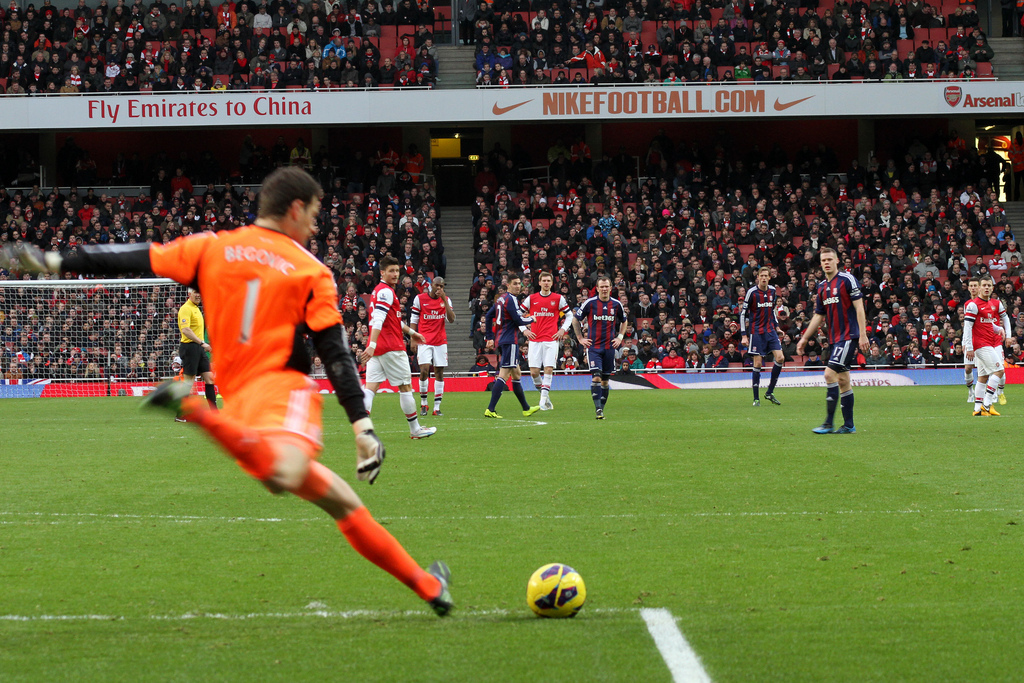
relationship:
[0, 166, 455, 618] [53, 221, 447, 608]
man in uniform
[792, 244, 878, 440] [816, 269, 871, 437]
player in uniform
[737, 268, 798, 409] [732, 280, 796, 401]
player in uniform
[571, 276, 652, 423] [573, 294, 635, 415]
player in uniform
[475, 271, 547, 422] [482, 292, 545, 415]
player in uniform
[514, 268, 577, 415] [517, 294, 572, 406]
player in uniform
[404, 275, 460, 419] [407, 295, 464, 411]
player in uniform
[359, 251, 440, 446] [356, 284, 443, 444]
player in uniform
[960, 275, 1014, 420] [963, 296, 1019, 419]
player in uniform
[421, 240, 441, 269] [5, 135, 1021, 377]
spectator in stand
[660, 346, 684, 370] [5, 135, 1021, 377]
spectator in stand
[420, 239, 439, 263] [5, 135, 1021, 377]
spectator in stand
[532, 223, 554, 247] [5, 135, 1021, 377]
spectator in stand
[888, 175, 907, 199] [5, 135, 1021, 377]
spectator in stand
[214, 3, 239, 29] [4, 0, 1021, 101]
spectator in stand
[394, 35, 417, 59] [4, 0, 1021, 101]
spectator in stand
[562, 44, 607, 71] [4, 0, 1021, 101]
spectator in stand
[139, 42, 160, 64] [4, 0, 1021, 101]
spectator in stand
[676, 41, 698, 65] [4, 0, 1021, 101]
spectator in stand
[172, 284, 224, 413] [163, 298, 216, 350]
man in shirt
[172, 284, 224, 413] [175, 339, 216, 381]
man in pants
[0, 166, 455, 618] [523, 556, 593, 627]
man kicking ball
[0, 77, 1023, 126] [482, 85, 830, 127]
billboard advertises nike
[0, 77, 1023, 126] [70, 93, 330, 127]
billboard advertises emirate airlines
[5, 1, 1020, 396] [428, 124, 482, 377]
stadium has stairwell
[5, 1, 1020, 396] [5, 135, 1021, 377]
stadium has stand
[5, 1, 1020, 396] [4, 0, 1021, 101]
stadium has stand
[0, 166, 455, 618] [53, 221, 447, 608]
man wearing uniform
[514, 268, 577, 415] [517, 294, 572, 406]
player wearing uniform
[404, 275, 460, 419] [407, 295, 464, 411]
player wearing uniform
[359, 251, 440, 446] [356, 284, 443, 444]
player wearing uniform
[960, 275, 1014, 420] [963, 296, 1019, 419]
player wearing uniform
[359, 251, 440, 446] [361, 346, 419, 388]
player wearing shorts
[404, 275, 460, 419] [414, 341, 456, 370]
player wearing shorts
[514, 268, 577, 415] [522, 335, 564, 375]
player wearing shorts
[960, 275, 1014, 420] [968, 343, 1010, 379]
player wearing shorts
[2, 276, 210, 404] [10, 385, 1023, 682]
net on field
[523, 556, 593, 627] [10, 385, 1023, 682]
ball on field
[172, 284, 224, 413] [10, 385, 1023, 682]
man on field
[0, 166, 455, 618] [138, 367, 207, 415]
man wearing cleats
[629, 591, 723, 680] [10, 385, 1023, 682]
line on field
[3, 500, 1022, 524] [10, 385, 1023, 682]
line on field